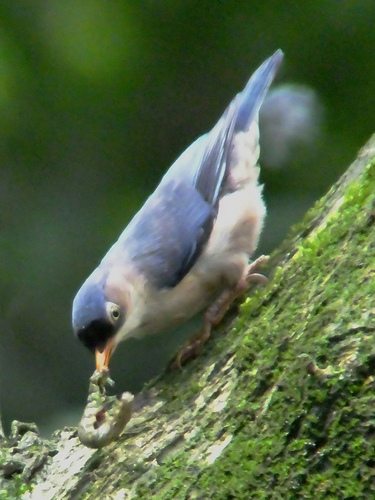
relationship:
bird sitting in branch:
[83, 178, 306, 342] [117, 225, 356, 490]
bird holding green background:
[72, 49, 284, 374] [2, 0, 375, 432]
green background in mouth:
[2, 0, 375, 432] [94, 344, 113, 371]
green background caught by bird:
[2, 0, 375, 432] [37, 94, 348, 362]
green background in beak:
[2, 0, 375, 432] [95, 347, 111, 371]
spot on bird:
[78, 314, 118, 344] [14, 67, 316, 342]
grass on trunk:
[198, 316, 375, 500] [210, 234, 357, 466]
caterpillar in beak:
[69, 364, 141, 451] [95, 347, 111, 371]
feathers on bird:
[167, 140, 223, 216] [50, 36, 300, 393]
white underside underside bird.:
[213, 124, 266, 291] [67, 48, 294, 375]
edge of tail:
[272, 46, 289, 59] [226, 41, 297, 129]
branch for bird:
[166, 254, 271, 374] [66, 49, 313, 378]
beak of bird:
[91, 353, 110, 364] [66, 45, 287, 342]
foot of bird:
[170, 253, 270, 370] [72, 49, 284, 374]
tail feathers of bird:
[207, 43, 293, 148] [72, 49, 284, 374]